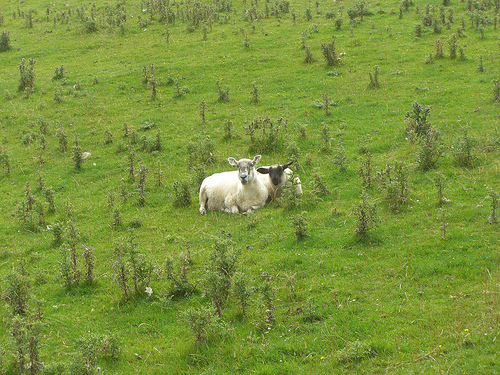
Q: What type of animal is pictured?
A: Sheep.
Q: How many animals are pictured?
A: Two.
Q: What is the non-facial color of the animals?
A: White.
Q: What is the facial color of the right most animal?
A: Black.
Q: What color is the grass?
A: Green.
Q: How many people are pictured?
A: None.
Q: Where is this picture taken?
A: In a field.